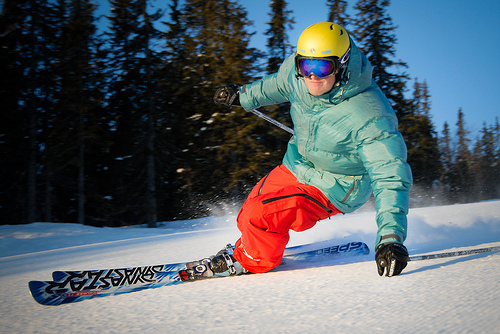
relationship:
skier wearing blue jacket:
[204, 12, 428, 282] [238, 35, 414, 244]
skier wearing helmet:
[204, 12, 428, 282] [296, 19, 353, 59]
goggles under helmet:
[293, 55, 340, 75] [298, 22, 347, 60]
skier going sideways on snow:
[179, 12, 443, 297] [0, 197, 497, 332]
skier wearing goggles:
[204, 12, 428, 282] [292, 51, 340, 78]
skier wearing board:
[204, 12, 428, 282] [29, 238, 389, 305]